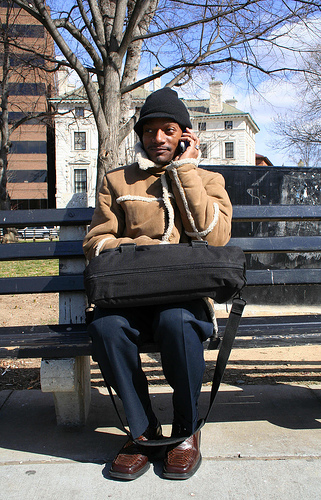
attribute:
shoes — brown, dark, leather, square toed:
[102, 444, 200, 483]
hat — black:
[141, 86, 185, 120]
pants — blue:
[102, 321, 205, 424]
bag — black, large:
[89, 245, 241, 296]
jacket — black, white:
[101, 179, 224, 234]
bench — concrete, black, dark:
[248, 201, 315, 300]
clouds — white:
[237, 66, 295, 117]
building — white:
[201, 90, 253, 163]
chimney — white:
[206, 74, 231, 114]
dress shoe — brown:
[165, 448, 194, 476]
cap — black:
[156, 86, 178, 112]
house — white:
[146, 77, 243, 101]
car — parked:
[19, 226, 60, 237]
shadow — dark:
[12, 399, 62, 450]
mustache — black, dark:
[154, 146, 170, 150]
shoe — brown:
[161, 442, 211, 487]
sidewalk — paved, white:
[247, 319, 298, 363]